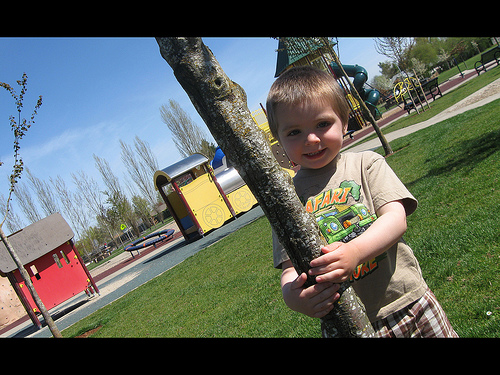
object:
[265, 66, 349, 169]
head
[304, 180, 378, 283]
arms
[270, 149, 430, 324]
shirt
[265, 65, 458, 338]
kid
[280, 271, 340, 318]
hand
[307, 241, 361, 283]
hand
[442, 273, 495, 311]
grass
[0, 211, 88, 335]
building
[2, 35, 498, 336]
land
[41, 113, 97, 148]
clouds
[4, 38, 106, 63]
sky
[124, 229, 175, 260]
trampoline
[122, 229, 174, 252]
train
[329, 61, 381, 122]
slide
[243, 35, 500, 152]
playground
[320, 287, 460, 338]
shorts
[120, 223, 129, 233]
sign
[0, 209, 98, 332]
play house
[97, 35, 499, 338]
park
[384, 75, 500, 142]
path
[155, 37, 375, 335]
tree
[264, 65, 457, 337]
boy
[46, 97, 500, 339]
field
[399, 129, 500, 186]
shadow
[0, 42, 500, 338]
ground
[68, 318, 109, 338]
mulch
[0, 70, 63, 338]
tree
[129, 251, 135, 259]
leg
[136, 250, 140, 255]
leg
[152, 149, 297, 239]
train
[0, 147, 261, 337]
playground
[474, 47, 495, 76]
bench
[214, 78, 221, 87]
hole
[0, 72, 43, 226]
tree branch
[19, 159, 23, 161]
leaf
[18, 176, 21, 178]
leaf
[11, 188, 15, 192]
leaf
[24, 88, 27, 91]
leaf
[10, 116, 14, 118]
leaf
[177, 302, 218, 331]
grass